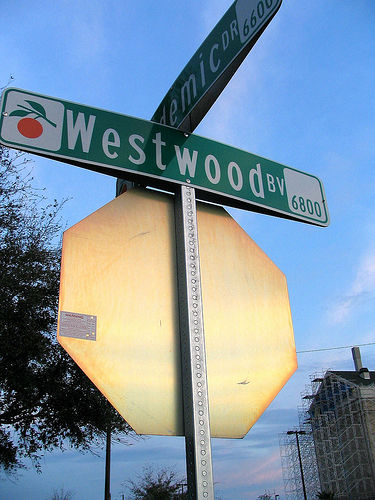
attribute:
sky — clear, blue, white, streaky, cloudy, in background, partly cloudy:
[0, 1, 373, 500]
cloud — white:
[321, 251, 374, 328]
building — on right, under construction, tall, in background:
[307, 346, 374, 499]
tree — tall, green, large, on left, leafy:
[0, 73, 152, 489]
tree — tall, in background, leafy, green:
[120, 462, 187, 500]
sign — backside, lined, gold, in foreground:
[57, 185, 299, 441]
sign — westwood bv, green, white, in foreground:
[2, 85, 329, 228]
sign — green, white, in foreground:
[115, 3, 283, 197]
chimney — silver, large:
[351, 346, 363, 371]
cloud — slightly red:
[241, 449, 286, 483]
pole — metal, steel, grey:
[174, 185, 216, 499]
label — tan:
[58, 309, 99, 343]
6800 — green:
[289, 194, 323, 218]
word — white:
[65, 110, 266, 200]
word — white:
[265, 174, 286, 196]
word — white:
[157, 43, 222, 127]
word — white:
[220, 19, 242, 51]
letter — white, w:
[67, 109, 99, 153]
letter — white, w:
[173, 144, 200, 178]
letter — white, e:
[102, 128, 121, 159]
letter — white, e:
[167, 99, 179, 127]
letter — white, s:
[126, 133, 147, 166]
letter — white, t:
[151, 131, 167, 171]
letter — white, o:
[203, 154, 223, 186]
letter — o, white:
[226, 162, 246, 193]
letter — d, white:
[247, 162, 267, 201]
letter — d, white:
[220, 30, 232, 51]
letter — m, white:
[179, 74, 200, 114]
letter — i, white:
[197, 51, 208, 88]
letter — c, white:
[208, 43, 223, 72]